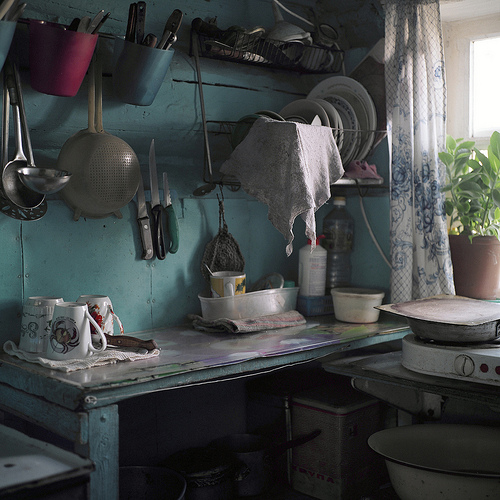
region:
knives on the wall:
[126, 135, 191, 269]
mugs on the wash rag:
[17, 287, 128, 366]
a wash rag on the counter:
[36, 352, 164, 384]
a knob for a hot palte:
[451, 353, 476, 378]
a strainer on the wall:
[63, 45, 140, 225]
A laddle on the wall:
[10, 70, 74, 198]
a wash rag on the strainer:
[237, 107, 343, 242]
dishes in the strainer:
[267, 67, 380, 171]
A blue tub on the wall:
[106, 33, 173, 110]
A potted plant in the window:
[437, 134, 499, 300]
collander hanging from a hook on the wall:
[55, 51, 142, 216]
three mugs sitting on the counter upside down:
[14, 281, 136, 363]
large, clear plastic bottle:
[320, 193, 363, 283]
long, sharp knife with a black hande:
[145, 135, 172, 257]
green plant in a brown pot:
[438, 127, 498, 302]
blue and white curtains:
[382, 7, 459, 304]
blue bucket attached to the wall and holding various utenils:
[117, 6, 187, 109]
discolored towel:
[188, 311, 309, 334]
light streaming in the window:
[470, 41, 499, 118]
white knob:
[456, 353, 476, 376]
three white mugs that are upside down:
[9, 285, 150, 375]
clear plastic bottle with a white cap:
[321, 194, 359, 289]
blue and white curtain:
[376, 5, 467, 302]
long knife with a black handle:
[145, 132, 172, 259]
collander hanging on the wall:
[57, 71, 147, 237]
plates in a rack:
[283, 74, 392, 173]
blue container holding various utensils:
[116, 3, 196, 120]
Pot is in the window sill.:
[427, 138, 497, 248]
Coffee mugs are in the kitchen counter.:
[26, 286, 123, 368]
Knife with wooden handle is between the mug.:
[80, 323, 157, 362]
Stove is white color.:
[394, 323, 498, 380]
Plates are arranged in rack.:
[291, 71, 380, 163]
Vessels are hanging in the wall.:
[3, 68, 136, 232]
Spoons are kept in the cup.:
[122, 3, 185, 108]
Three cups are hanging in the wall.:
[0, 16, 180, 76]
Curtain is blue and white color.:
[388, 19, 450, 293]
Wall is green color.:
[24, 226, 139, 291]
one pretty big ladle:
[8, 43, 77, 205]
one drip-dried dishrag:
[222, 113, 355, 263]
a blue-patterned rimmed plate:
[318, 89, 360, 164]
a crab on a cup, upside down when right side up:
[43, 308, 84, 354]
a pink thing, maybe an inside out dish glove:
[331, 154, 385, 182]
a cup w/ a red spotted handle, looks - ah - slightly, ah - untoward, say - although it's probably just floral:
[78, 288, 131, 343]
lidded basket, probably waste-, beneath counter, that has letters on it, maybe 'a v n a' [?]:
[281, 383, 396, 498]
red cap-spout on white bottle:
[306, 230, 328, 249]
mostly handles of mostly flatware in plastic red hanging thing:
[30, 3, 113, 33]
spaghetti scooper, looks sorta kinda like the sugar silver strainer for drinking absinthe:
[0, 76, 61, 223]